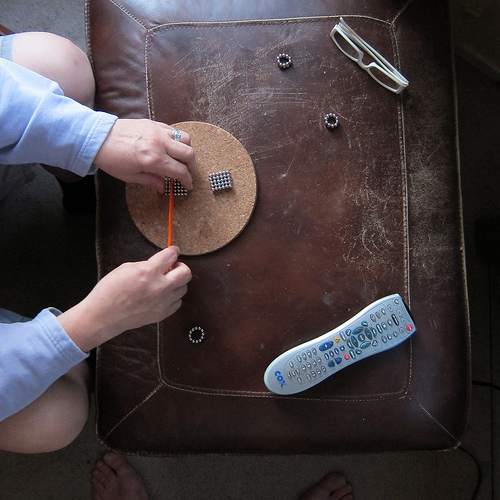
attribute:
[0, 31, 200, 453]
person — sitting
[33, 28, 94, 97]
knee — white, hairless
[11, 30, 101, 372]
person — sitting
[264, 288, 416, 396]
remote — silver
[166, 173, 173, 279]
device — orange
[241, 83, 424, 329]
leather ottoman — brown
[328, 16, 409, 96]
glasses — white-rimmed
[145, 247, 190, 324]
fingers — white, holding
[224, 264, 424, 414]
remote — grey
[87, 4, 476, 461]
leather ottoman — worn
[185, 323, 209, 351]
object — circular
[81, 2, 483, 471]
ottoman — brown, leather, worn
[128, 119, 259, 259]
cutting board — circular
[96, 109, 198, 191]
hand — white, closed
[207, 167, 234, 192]
object — black and white, square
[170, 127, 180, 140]
ring — silver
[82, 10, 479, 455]
table — old